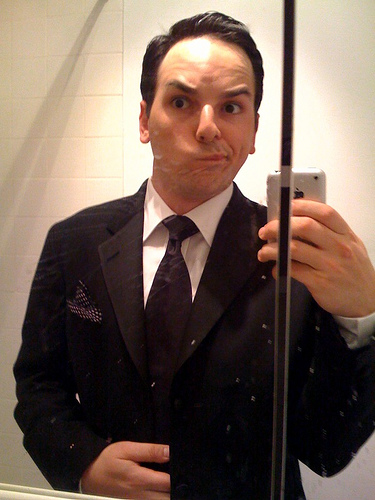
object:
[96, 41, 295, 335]
man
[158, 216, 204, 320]
tie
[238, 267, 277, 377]
mirror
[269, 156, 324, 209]
phone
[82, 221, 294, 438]
suit